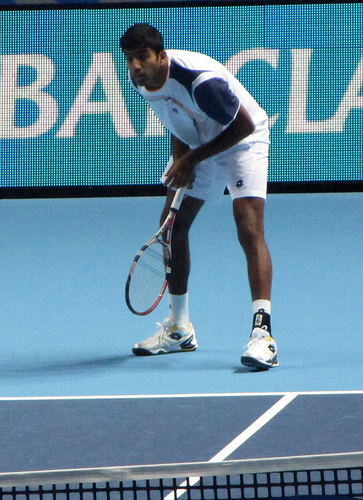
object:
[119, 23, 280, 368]
man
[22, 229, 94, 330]
court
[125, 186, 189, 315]
racket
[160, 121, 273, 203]
shorts